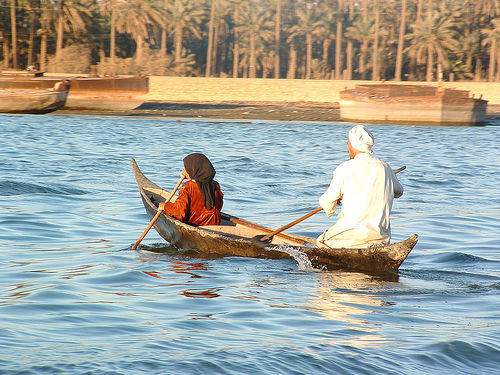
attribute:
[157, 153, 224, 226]
woman — riding, dressed, reflected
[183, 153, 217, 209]
scarf — black, brown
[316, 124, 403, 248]
man — riding, dressed, reflected, rowing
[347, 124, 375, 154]
turban — white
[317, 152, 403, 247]
robe — white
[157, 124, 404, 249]
couple — riding, reflected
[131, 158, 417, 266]
boat — brown, wooden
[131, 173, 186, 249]
oar — wooden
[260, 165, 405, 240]
oar — wooden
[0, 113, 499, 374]
water — rippling, calm, blue, splashing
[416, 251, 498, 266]
wave — small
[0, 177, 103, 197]
wave — small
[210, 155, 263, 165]
wave — small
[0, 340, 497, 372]
wave — small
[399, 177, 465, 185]
wave — small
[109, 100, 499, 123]
dirt — dark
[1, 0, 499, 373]
image — beautiful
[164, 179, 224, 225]
shirt — brown, orange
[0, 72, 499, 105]
sand — light tan